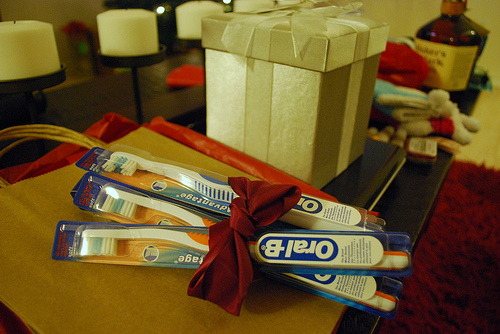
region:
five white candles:
[0, 0, 310, 102]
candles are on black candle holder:
[5, 54, 220, 125]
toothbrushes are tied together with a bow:
[180, 142, 284, 332]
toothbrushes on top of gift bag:
[59, 140, 443, 316]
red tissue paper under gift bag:
[52, 97, 319, 172]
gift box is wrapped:
[197, 25, 424, 161]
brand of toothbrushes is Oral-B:
[254, 217, 354, 280]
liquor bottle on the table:
[410, 14, 495, 107]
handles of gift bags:
[10, 117, 99, 160]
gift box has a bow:
[228, 13, 386, 58]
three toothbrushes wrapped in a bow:
[48, 138, 423, 323]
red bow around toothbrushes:
[189, 161, 309, 311]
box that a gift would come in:
[189, 6, 394, 194]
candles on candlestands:
[3, 13, 176, 138]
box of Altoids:
[396, 131, 446, 166]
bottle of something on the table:
[417, 2, 491, 109]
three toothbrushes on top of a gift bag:
[2, 117, 422, 327]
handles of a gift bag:
[0, 121, 112, 146]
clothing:
[384, 44, 476, 154]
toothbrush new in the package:
[55, 215, 412, 275]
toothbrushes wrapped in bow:
[55, 125, 430, 301]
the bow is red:
[171, 171, 304, 303]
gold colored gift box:
[187, 9, 415, 203]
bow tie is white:
[221, 0, 370, 200]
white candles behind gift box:
[1, 2, 266, 87]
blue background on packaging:
[253, 230, 368, 260]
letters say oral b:
[259, 233, 336, 264]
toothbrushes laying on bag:
[1, 84, 393, 320]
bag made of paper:
[6, 140, 348, 332]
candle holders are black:
[0, 64, 90, 103]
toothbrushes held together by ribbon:
[48, 127, 415, 317]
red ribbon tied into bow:
[198, 167, 298, 307]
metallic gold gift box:
[197, 1, 391, 191]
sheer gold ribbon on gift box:
[220, 2, 370, 70]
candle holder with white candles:
[0, 9, 157, 136]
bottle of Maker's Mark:
[414, 0, 489, 97]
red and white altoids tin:
[408, 132, 440, 159]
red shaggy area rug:
[452, 177, 492, 281]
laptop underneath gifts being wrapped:
[350, 121, 412, 226]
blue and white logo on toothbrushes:
[259, 235, 348, 268]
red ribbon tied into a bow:
[190, 165, 298, 324]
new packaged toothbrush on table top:
[42, 205, 404, 301]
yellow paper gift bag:
[5, 116, 255, 332]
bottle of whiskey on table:
[407, 4, 489, 101]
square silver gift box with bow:
[190, 6, 388, 204]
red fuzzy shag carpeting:
[420, 155, 488, 320]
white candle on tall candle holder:
[75, 5, 178, 112]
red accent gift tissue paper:
[70, 99, 309, 201]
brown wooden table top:
[353, 149, 443, 204]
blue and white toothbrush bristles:
[100, 150, 151, 183]